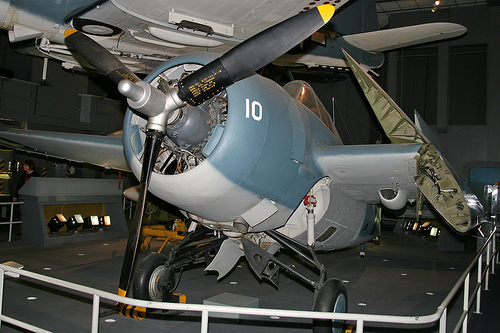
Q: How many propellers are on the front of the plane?
A: Three.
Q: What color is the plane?
A: Silver.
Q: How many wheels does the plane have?
A: Two.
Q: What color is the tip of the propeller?
A: Yellow.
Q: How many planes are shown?
A: One.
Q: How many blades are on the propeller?
A: Three.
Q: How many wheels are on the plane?
A: Two.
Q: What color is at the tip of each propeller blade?
A: Yellow.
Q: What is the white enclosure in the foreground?
A: Railing.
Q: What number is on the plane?
A: Ten.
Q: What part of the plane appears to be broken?
A: Wing.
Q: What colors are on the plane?
A: Blue and white.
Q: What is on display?
A: Old airplane.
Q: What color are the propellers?
A: Black and yellow.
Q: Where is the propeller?
A: On the front of the plane.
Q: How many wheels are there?
A: Two.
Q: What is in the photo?
A: An aircraft.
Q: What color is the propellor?
A: Black and yellow.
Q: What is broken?
A: Wing of plane.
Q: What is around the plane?
A: A rail.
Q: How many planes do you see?
A: 1.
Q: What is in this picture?
A: A plane.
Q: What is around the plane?
A: A white fence.